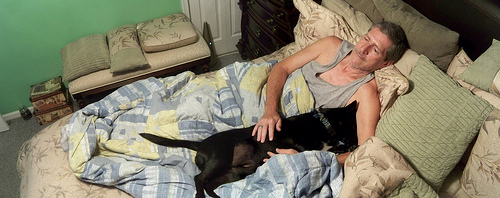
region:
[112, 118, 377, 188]
dog laying in the bed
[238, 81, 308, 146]
man petting a dog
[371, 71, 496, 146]
green pillow on the bed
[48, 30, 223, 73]
three pillows on the bench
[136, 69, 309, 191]
man under a blue blanket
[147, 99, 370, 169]
dog on top of a blanket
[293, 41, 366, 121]
man wearing a tank top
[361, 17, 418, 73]
man with gray hair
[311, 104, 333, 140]
man with a collar on its neck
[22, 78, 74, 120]
stack of books on the floor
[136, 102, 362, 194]
Dog on bed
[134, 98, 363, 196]
Dog is on bed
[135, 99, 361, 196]
Dog laying on bed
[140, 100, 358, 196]
Dog is laying on bed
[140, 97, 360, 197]
Black dog on bed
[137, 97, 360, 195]
Black dog is on bed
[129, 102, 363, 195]
Black dog laying in bed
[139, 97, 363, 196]
Black dog is laying in bed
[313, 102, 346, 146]
Dog wearing a collar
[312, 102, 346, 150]
Dog is wearing a collar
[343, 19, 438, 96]
the head of a man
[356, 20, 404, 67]
the eyes of a man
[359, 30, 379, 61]
the nose of a man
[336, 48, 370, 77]
the mouth of a man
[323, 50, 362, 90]
the chin of a man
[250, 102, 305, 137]
the hand of a man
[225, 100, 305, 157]
the fingers of a man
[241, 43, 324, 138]
the arm of a man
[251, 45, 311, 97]
the elbow of a man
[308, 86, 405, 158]
the head of a dog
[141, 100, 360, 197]
a black dog sleeping on a bed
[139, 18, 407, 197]
a man sleeping next to a black dog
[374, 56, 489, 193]
a green cushion on a bed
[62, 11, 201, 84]
green cushions on a bench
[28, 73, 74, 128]
two painted boxes on top of each other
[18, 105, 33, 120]
a small glass jar on the ground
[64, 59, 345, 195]
a rumpled blanket on a bed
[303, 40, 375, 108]
man wearing a gray tank top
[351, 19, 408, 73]
man with brown and gray hair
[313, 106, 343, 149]
a black and white dog collar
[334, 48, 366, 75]
the chin of a man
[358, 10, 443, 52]
the hair of a man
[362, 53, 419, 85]
the ear of a man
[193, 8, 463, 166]
a man in the bed